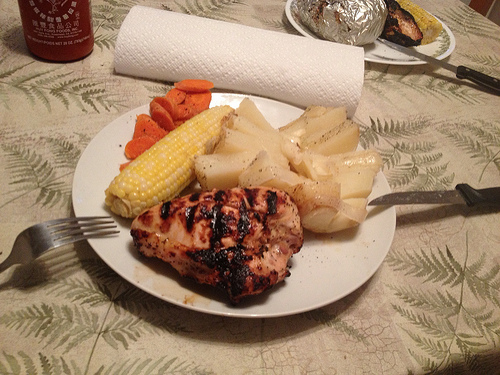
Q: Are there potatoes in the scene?
A: Yes, there is a potato.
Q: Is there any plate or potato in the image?
A: Yes, there is a potato.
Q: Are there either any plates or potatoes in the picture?
A: Yes, there is a potato.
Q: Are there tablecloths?
A: Yes, there is a tablecloth.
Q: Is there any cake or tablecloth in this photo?
A: Yes, there is a tablecloth.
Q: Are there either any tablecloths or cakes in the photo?
A: Yes, there is a tablecloth.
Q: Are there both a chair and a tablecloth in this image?
A: No, there is a tablecloth but no chairs.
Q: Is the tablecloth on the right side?
A: No, the tablecloth is on the left of the image.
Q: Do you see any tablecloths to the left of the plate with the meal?
A: Yes, there is a tablecloth to the left of the plate.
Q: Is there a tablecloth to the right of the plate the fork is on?
A: No, the tablecloth is to the left of the plate.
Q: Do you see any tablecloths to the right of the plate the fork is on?
A: No, the tablecloth is to the left of the plate.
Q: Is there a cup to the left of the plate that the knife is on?
A: No, there is a tablecloth to the left of the plate.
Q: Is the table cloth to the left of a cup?
A: No, the table cloth is to the left of the plate.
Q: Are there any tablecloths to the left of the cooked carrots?
A: Yes, there is a tablecloth to the left of the carrots.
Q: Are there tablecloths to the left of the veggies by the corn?
A: Yes, there is a tablecloth to the left of the carrots.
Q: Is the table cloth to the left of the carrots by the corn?
A: Yes, the table cloth is to the left of the carrots.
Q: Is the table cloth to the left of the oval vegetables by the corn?
A: Yes, the table cloth is to the left of the carrots.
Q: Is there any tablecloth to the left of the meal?
A: Yes, there is a tablecloth to the left of the meal.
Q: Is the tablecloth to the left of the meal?
A: Yes, the tablecloth is to the left of the meal.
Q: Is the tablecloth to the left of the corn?
A: Yes, the tablecloth is to the left of the corn.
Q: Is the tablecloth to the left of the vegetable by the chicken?
A: Yes, the tablecloth is to the left of the corn.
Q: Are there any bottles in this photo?
A: Yes, there is a bottle.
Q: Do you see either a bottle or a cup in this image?
A: Yes, there is a bottle.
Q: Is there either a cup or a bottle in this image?
A: Yes, there is a bottle.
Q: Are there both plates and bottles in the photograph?
A: Yes, there are both a bottle and a plate.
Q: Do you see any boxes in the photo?
A: No, there are no boxes.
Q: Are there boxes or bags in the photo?
A: No, there are no boxes or bags.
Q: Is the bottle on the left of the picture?
A: Yes, the bottle is on the left of the image.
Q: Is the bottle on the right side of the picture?
A: No, the bottle is on the left of the image.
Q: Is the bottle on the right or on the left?
A: The bottle is on the left of the image.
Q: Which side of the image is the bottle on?
A: The bottle is on the left of the image.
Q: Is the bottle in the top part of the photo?
A: Yes, the bottle is in the top of the image.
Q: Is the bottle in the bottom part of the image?
A: No, the bottle is in the top of the image.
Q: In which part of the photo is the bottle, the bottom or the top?
A: The bottle is in the top of the image.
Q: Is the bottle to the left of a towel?
A: Yes, the bottle is to the left of a towel.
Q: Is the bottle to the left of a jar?
A: No, the bottle is to the left of a towel.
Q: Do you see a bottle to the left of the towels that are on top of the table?
A: Yes, there is a bottle to the left of the towels.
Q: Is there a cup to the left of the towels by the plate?
A: No, there is a bottle to the left of the towels.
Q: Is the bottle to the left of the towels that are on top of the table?
A: Yes, the bottle is to the left of the towels.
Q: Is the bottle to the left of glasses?
A: No, the bottle is to the left of the towels.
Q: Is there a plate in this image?
A: Yes, there is a plate.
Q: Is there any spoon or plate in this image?
A: Yes, there is a plate.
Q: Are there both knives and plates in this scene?
A: Yes, there are both a plate and a knife.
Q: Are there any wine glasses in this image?
A: No, there are no wine glasses.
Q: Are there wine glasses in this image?
A: No, there are no wine glasses.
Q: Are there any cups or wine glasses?
A: No, there are no wine glasses or cups.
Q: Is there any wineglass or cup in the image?
A: No, there are no wine glasses or cups.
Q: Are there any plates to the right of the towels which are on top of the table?
A: Yes, there is a plate to the right of the towels.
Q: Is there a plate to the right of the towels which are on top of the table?
A: Yes, there is a plate to the right of the towels.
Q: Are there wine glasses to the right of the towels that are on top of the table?
A: No, there is a plate to the right of the towels.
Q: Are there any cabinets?
A: No, there are no cabinets.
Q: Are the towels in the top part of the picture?
A: Yes, the towels are in the top of the image.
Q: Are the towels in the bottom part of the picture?
A: No, the towels are in the top of the image.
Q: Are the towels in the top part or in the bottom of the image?
A: The towels are in the top of the image.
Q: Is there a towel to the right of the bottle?
A: Yes, there are towels to the right of the bottle.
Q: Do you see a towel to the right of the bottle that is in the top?
A: Yes, there are towels to the right of the bottle.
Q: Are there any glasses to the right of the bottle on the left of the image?
A: No, there are towels to the right of the bottle.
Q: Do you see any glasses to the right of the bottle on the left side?
A: No, there are towels to the right of the bottle.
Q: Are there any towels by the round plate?
A: Yes, there are towels by the plate.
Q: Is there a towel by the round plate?
A: Yes, there are towels by the plate.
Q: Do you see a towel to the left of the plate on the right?
A: Yes, there are towels to the left of the plate.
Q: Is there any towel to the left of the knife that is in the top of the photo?
A: Yes, there are towels to the left of the knife.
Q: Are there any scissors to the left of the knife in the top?
A: No, there are towels to the left of the knife.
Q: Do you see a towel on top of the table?
A: Yes, there are towels on top of the table.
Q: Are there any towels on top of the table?
A: Yes, there are towels on top of the table.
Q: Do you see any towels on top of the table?
A: Yes, there are towels on top of the table.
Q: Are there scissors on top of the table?
A: No, there are towels on top of the table.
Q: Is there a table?
A: Yes, there is a table.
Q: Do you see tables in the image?
A: Yes, there is a table.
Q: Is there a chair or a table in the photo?
A: Yes, there is a table.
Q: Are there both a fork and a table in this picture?
A: Yes, there are both a table and a fork.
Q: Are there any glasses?
A: No, there are no glasses.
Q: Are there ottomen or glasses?
A: No, there are no glasses or ottomen.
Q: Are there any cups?
A: No, there are no cups.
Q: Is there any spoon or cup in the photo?
A: No, there are no cups or spoons.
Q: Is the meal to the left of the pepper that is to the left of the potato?
A: Yes, the meal is to the left of the pepper.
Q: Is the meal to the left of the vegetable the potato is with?
A: Yes, the meal is to the left of the pepper.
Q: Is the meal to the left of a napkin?
A: No, the meal is to the left of the pepper.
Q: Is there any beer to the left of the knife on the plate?
A: No, there is meal to the left of the knife.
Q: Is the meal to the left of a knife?
A: Yes, the meal is to the left of a knife.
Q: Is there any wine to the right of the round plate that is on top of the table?
A: No, there is meal to the right of the plate.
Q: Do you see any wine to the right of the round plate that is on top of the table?
A: No, there is meal to the right of the plate.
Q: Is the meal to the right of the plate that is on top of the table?
A: Yes, the meal is to the right of the plate.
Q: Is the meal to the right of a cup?
A: No, the meal is to the right of the plate.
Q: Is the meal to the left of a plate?
A: No, the meal is to the right of a plate.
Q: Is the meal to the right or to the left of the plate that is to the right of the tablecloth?
A: The meal is to the right of the plate.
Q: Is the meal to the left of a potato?
A: Yes, the meal is to the left of a potato.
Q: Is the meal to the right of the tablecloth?
A: Yes, the meal is to the right of the tablecloth.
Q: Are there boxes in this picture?
A: No, there are no boxes.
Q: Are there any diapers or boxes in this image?
A: No, there are no boxes or diapers.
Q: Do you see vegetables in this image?
A: Yes, there are vegetables.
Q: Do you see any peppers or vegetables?
A: Yes, there are vegetables.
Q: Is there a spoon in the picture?
A: No, there are no spoons.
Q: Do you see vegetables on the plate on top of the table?
A: Yes, there are vegetables on the plate.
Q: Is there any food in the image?
A: Yes, there is food.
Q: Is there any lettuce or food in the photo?
A: Yes, there is food.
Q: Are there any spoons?
A: No, there are no spoons.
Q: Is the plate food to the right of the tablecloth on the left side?
A: Yes, the food is to the right of the table cloth.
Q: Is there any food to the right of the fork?
A: Yes, there is food to the right of the fork.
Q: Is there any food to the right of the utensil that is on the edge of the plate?
A: Yes, there is food to the right of the fork.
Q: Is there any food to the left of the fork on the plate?
A: No, the food is to the right of the fork.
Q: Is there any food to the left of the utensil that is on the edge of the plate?
A: No, the food is to the right of the fork.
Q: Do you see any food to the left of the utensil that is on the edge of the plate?
A: No, the food is to the right of the fork.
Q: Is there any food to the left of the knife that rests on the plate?
A: Yes, there is food to the left of the knife.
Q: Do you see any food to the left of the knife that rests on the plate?
A: Yes, there is food to the left of the knife.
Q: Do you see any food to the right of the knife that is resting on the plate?
A: No, the food is to the left of the knife.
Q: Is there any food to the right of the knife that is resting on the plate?
A: No, the food is to the left of the knife.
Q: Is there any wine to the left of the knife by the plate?
A: No, there is food to the left of the knife.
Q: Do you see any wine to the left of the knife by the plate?
A: No, there is food to the left of the knife.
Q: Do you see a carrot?
A: Yes, there are carrots.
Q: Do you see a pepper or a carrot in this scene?
A: Yes, there are carrots.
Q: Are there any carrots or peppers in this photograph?
A: Yes, there are carrots.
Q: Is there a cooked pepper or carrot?
A: Yes, there are cooked carrots.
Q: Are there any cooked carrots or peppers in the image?
A: Yes, there are cooked carrots.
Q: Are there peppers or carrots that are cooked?
A: Yes, the carrots are cooked.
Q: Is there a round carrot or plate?
A: Yes, there are round carrots.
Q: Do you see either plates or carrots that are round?
A: Yes, the carrots are round.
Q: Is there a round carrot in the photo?
A: Yes, there are round carrots.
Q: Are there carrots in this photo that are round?
A: Yes, there are carrots that are round.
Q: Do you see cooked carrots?
A: Yes, there are cooked carrots.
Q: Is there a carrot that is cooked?
A: Yes, there are carrots that are cooked.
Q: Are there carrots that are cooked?
A: Yes, there are carrots that are cooked.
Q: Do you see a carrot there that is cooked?
A: Yes, there are carrots that are cooked.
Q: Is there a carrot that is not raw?
A: Yes, there are cooked carrots.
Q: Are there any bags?
A: No, there are no bags.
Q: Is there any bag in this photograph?
A: No, there are no bags.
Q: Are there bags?
A: No, there are no bags.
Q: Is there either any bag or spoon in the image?
A: No, there are no bags or spoons.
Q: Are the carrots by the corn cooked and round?
A: Yes, the carrots are cooked and round.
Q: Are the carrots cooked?
A: Yes, the carrots are cooked.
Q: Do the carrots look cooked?
A: Yes, the carrots are cooked.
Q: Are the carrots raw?
A: No, the carrots are cooked.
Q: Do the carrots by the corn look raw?
A: No, the carrots are cooked.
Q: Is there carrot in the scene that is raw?
A: No, there are carrots but they are cooked.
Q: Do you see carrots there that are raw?
A: No, there are carrots but they are cooked.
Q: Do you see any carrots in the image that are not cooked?
A: No, there are carrots but they are cooked.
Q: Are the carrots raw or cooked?
A: The carrots are cooked.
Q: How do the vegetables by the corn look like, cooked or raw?
A: The carrots are cooked.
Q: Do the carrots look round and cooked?
A: Yes, the carrots are round and cooked.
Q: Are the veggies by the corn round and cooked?
A: Yes, the carrots are round and cooked.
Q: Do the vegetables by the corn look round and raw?
A: No, the carrots are round but cooked.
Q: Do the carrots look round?
A: Yes, the carrots are round.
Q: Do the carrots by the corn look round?
A: Yes, the carrots are round.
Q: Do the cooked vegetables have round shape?
A: Yes, the carrots are round.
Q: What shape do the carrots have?
A: The carrots have round shape.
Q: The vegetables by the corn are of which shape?
A: The carrots are round.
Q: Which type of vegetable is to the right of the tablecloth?
A: The vegetables are carrots.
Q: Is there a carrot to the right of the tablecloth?
A: Yes, there are carrots to the right of the tablecloth.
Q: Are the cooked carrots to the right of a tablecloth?
A: Yes, the carrots are to the right of a tablecloth.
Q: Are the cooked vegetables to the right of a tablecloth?
A: Yes, the carrots are to the right of a tablecloth.